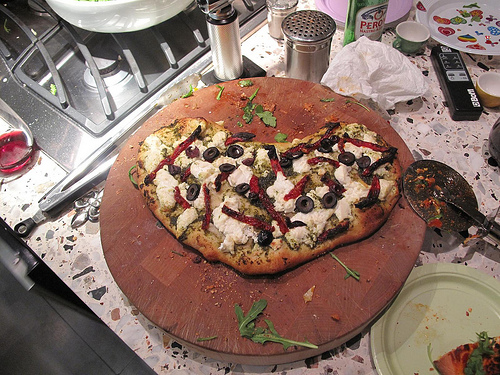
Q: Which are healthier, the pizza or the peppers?
A: The peppers are healthier than the pizza.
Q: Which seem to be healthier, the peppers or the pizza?
A: The peppers are healthier than the pizza.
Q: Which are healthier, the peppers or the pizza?
A: The peppers are healthier than the pizza.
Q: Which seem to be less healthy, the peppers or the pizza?
A: The pizza are less healthy than the peppers.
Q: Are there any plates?
A: Yes, there is a plate.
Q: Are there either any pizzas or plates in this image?
A: Yes, there is a plate.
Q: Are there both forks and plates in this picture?
A: No, there is a plate but no forks.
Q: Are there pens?
A: No, there are no pens.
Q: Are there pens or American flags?
A: No, there are no pens or American flags.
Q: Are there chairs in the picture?
A: No, there are no chairs.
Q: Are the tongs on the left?
A: Yes, the tongs are on the left of the image.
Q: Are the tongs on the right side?
A: No, the tongs are on the left of the image.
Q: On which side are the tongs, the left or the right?
A: The tongs are on the left of the image.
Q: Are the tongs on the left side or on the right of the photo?
A: The tongs are on the left of the image.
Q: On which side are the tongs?
A: The tongs are on the left of the image.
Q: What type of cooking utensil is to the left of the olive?
A: The cooking utensils are tongs.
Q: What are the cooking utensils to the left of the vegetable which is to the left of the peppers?
A: The cooking utensils are tongs.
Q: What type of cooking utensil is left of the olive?
A: The cooking utensils are tongs.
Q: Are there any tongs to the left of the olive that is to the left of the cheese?
A: Yes, there are tongs to the left of the olive.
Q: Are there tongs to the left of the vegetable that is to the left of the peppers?
A: Yes, there are tongs to the left of the olive.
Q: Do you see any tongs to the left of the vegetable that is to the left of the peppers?
A: Yes, there are tongs to the left of the olive.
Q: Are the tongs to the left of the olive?
A: Yes, the tongs are to the left of the olive.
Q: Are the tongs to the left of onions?
A: No, the tongs are to the left of the olives.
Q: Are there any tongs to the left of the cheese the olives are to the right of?
A: Yes, there are tongs to the left of the cheese.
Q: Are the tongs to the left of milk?
A: No, the tongs are to the left of the cheese.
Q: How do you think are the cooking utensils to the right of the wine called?
A: The cooking utensils are tongs.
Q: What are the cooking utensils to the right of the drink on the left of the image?
A: The cooking utensils are tongs.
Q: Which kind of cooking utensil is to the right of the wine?
A: The cooking utensils are tongs.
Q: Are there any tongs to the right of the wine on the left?
A: Yes, there are tongs to the right of the wine.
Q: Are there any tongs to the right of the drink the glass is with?
A: Yes, there are tongs to the right of the wine.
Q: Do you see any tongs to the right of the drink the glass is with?
A: Yes, there are tongs to the right of the wine.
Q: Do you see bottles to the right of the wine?
A: No, there are tongs to the right of the wine.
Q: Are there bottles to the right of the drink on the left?
A: No, there are tongs to the right of the wine.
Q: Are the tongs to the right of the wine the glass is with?
A: Yes, the tongs are to the right of the wine.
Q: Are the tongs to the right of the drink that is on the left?
A: Yes, the tongs are to the right of the wine.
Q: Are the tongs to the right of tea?
A: No, the tongs are to the right of the wine.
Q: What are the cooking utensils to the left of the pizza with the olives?
A: The cooking utensils are tongs.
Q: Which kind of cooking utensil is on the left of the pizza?
A: The cooking utensils are tongs.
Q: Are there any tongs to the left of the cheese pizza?
A: Yes, there are tongs to the left of the pizza.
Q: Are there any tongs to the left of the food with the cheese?
A: Yes, there are tongs to the left of the pizza.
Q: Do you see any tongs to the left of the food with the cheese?
A: Yes, there are tongs to the left of the pizza.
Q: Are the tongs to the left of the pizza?
A: Yes, the tongs are to the left of the pizza.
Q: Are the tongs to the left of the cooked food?
A: Yes, the tongs are to the left of the pizza.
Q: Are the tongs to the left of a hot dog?
A: No, the tongs are to the left of the pizza.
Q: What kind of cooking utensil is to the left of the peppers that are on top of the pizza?
A: The cooking utensils are tongs.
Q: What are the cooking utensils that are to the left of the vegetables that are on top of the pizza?
A: The cooking utensils are tongs.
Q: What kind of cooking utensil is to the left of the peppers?
A: The cooking utensils are tongs.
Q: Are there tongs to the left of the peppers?
A: Yes, there are tongs to the left of the peppers.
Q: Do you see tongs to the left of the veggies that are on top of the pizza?
A: Yes, there are tongs to the left of the peppers.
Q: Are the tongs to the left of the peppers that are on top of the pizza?
A: Yes, the tongs are to the left of the peppers.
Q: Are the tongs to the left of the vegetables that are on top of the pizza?
A: Yes, the tongs are to the left of the peppers.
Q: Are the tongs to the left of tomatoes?
A: No, the tongs are to the left of the peppers.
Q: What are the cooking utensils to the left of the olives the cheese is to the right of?
A: The cooking utensils are tongs.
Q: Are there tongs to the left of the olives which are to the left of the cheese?
A: Yes, there are tongs to the left of the olives.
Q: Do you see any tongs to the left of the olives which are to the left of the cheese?
A: Yes, there are tongs to the left of the olives.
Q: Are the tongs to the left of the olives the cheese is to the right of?
A: Yes, the tongs are to the left of the olives.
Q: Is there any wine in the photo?
A: Yes, there is wine.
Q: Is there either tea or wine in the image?
A: Yes, there is wine.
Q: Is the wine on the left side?
A: Yes, the wine is on the left of the image.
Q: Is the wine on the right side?
A: No, the wine is on the left of the image.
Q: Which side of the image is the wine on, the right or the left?
A: The wine is on the left of the image.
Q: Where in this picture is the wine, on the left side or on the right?
A: The wine is on the left of the image.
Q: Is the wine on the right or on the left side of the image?
A: The wine is on the left of the image.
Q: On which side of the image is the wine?
A: The wine is on the left of the image.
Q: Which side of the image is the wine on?
A: The wine is on the left of the image.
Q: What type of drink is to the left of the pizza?
A: The drink is wine.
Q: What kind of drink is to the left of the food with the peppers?
A: The drink is wine.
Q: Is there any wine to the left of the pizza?
A: Yes, there is wine to the left of the pizza.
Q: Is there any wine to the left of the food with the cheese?
A: Yes, there is wine to the left of the pizza.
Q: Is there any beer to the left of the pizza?
A: No, there is wine to the left of the pizza.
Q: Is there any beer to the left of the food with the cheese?
A: No, there is wine to the left of the pizza.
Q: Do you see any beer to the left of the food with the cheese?
A: No, there is wine to the left of the pizza.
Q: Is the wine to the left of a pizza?
A: Yes, the wine is to the left of a pizza.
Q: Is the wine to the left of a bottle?
A: No, the wine is to the left of a pizza.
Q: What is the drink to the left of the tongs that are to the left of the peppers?
A: The drink is wine.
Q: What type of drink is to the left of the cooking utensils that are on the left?
A: The drink is wine.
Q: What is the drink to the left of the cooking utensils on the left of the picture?
A: The drink is wine.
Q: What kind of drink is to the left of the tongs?
A: The drink is wine.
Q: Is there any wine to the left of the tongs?
A: Yes, there is wine to the left of the tongs.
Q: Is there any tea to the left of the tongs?
A: No, there is wine to the left of the tongs.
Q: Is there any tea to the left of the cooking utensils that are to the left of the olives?
A: No, there is wine to the left of the tongs.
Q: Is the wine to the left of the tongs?
A: Yes, the wine is to the left of the tongs.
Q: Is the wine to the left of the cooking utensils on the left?
A: Yes, the wine is to the left of the tongs.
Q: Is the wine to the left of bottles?
A: No, the wine is to the left of the tongs.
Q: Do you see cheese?
A: Yes, there is cheese.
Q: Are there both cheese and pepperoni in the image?
A: No, there is cheese but no pepperoni.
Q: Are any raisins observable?
A: No, there are no raisins.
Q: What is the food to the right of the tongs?
A: The food is cheese.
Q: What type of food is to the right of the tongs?
A: The food is cheese.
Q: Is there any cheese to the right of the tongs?
A: Yes, there is cheese to the right of the tongs.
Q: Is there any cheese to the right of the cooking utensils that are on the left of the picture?
A: Yes, there is cheese to the right of the tongs.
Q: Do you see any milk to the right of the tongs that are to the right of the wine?
A: No, there is cheese to the right of the tongs.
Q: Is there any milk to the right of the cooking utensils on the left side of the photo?
A: No, there is cheese to the right of the tongs.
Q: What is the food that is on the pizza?
A: The food is cheese.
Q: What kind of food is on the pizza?
A: The food is cheese.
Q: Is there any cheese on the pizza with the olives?
A: Yes, there is cheese on the pizza.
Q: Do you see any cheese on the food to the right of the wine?
A: Yes, there is cheese on the pizza.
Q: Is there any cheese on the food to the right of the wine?
A: Yes, there is cheese on the pizza.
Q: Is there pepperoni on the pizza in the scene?
A: No, there is cheese on the pizza.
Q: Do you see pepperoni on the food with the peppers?
A: No, there is cheese on the pizza.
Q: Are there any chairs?
A: No, there are no chairs.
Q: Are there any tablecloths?
A: No, there are no tablecloths.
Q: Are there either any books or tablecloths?
A: No, there are no tablecloths or books.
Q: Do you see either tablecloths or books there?
A: No, there are no tablecloths or books.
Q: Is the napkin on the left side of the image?
A: No, the napkin is on the right of the image.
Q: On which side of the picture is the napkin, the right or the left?
A: The napkin is on the right of the image.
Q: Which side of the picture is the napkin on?
A: The napkin is on the right of the image.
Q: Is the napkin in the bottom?
A: No, the napkin is in the top of the image.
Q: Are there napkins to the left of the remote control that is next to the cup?
A: Yes, there is a napkin to the left of the remote.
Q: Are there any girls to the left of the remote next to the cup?
A: No, there is a napkin to the left of the remote control.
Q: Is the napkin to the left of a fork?
A: No, the napkin is to the left of a remote control.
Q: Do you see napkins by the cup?
A: Yes, there is a napkin by the cup.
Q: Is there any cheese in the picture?
A: Yes, there is cheese.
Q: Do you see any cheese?
A: Yes, there is cheese.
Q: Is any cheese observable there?
A: Yes, there is cheese.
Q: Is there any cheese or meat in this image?
A: Yes, there is cheese.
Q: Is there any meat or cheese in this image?
A: Yes, there is cheese.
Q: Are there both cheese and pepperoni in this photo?
A: No, there is cheese but no pepperoni.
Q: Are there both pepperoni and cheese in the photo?
A: No, there is cheese but no pepperoni.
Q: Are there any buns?
A: No, there are no buns.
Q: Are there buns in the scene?
A: No, there are no buns.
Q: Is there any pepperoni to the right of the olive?
A: No, there is cheese to the right of the olive.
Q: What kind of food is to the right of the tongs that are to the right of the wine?
A: The food is cheese.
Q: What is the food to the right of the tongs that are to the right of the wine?
A: The food is cheese.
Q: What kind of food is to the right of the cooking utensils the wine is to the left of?
A: The food is cheese.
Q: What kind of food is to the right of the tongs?
A: The food is cheese.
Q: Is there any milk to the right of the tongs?
A: No, there is cheese to the right of the tongs.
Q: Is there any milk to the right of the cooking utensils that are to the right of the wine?
A: No, there is cheese to the right of the tongs.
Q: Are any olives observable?
A: Yes, there are olives.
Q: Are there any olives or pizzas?
A: Yes, there are olives.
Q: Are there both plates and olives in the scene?
A: Yes, there are both olives and a plate.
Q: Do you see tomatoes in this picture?
A: No, there are no tomatoes.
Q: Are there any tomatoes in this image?
A: No, there are no tomatoes.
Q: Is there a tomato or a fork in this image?
A: No, there are no tomatoes or forks.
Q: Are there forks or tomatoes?
A: No, there are no tomatoes or forks.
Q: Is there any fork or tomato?
A: No, there are no tomatoes or forks.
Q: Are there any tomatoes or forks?
A: No, there are no tomatoes or forks.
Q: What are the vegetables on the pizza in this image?
A: The vegetables are olives.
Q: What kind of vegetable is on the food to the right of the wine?
A: The vegetables are olives.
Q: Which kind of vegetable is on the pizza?
A: The vegetables are olives.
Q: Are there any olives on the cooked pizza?
A: Yes, there are olives on the pizza.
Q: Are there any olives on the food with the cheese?
A: Yes, there are olives on the pizza.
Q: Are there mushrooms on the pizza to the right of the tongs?
A: No, there are olives on the pizza.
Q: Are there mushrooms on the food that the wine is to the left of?
A: No, there are olives on the pizza.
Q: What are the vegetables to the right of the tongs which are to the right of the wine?
A: The vegetables are olives.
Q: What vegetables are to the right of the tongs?
A: The vegetables are olives.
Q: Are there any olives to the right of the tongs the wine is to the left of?
A: Yes, there are olives to the right of the tongs.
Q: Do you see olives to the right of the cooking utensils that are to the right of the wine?
A: Yes, there are olives to the right of the tongs.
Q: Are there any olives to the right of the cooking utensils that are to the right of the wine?
A: Yes, there are olives to the right of the tongs.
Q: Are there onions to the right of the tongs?
A: No, there are olives to the right of the tongs.